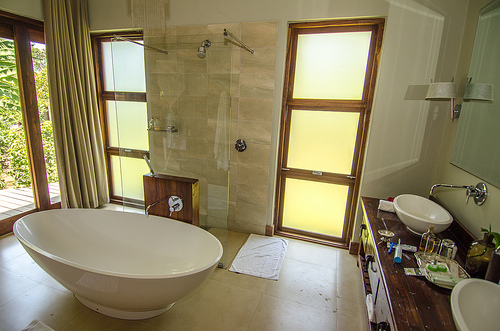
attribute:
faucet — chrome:
[428, 181, 486, 205]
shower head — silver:
[195, 37, 212, 59]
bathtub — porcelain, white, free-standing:
[12, 207, 223, 323]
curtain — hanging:
[42, 0, 112, 209]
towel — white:
[228, 229, 290, 283]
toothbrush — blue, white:
[392, 237, 404, 262]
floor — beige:
[0, 199, 370, 330]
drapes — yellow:
[40, 1, 111, 210]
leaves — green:
[1, 37, 58, 190]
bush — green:
[0, 38, 57, 191]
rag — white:
[365, 292, 375, 322]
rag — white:
[375, 196, 395, 214]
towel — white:
[19, 315, 54, 330]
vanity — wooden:
[355, 196, 477, 331]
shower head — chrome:
[195, 36, 212, 62]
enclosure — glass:
[109, 23, 289, 250]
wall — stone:
[141, 20, 280, 233]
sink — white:
[391, 193, 453, 238]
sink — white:
[449, 272, 499, 330]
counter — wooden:
[357, 193, 479, 329]